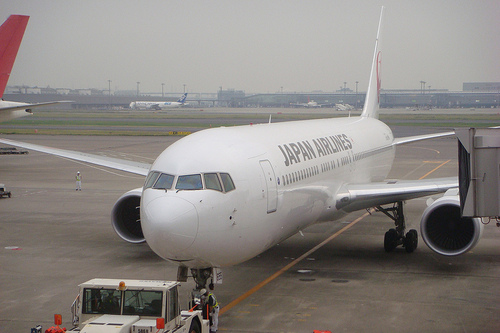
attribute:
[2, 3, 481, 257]
plane — white, red, white black, blue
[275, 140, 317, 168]
word — gray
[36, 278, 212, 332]
car — white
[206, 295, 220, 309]
vest — yellow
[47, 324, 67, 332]
cover — orange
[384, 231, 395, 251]
tire — black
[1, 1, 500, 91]
sky — hazy, cloudy, hazey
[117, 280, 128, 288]
light — off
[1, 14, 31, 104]
tail — red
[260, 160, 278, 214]
door — white